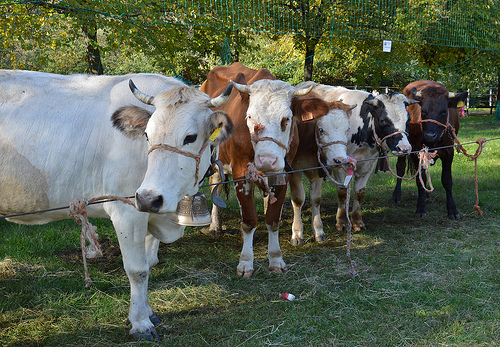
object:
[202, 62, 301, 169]
fur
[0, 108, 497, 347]
ground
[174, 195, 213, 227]
bell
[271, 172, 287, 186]
bell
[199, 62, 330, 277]
cow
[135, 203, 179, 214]
chin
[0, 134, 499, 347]
wire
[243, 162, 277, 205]
rope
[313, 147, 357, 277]
rope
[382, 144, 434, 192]
rope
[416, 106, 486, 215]
rope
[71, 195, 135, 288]
rope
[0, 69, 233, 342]
cattle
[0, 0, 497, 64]
fince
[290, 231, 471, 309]
hay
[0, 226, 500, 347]
grass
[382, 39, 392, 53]
sign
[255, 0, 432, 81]
tree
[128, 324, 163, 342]
hove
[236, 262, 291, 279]
hove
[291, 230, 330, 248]
hove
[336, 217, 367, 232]
hove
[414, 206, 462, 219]
hove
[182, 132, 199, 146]
eye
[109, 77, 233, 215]
head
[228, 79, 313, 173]
head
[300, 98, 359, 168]
head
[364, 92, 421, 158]
head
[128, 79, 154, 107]
horns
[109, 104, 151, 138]
ear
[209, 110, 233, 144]
ear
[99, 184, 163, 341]
leg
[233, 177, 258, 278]
leg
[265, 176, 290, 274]
leg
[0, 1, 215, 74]
tree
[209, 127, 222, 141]
tag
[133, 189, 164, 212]
nose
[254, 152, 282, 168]
nose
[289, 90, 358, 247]
cow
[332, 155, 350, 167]
nose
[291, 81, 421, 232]
cow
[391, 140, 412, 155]
nose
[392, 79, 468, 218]
cow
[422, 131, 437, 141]
nose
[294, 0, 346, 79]
part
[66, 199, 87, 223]
knot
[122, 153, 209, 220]
neck